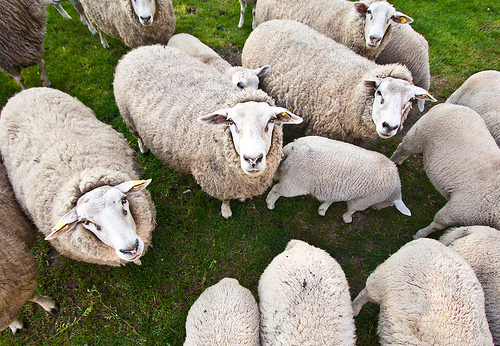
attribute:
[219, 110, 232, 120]
tag — yellow